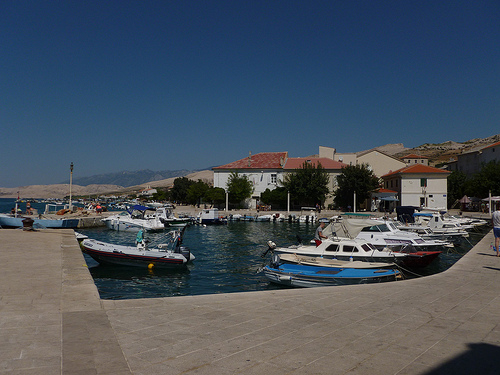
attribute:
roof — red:
[209, 147, 283, 173]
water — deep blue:
[177, 220, 270, 285]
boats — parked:
[263, 210, 450, 280]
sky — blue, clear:
[16, 10, 485, 123]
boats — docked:
[266, 259, 402, 289]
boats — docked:
[265, 236, 408, 267]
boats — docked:
[308, 212, 452, 257]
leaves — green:
[345, 173, 372, 190]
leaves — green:
[294, 175, 320, 189]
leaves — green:
[233, 184, 245, 197]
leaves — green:
[186, 185, 209, 203]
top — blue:
[266, 256, 399, 280]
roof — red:
[207, 148, 348, 174]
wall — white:
[244, 165, 286, 191]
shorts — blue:
[490, 225, 499, 237]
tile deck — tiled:
[6, 221, 500, 374]